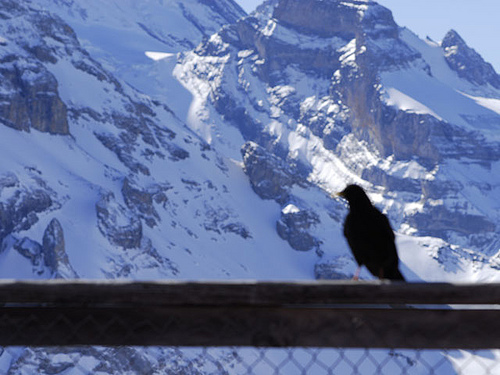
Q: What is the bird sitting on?
A: It is sitting on a railing.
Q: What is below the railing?
A: Open twisted wire fencing.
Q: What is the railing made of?
A: The pieces are made of wood which are separated.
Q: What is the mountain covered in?
A: Snow.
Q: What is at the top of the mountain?
A: A wide circular peak.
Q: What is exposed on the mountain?
A: Layers of rock.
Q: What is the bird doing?
A: The bird is profiling against the snowy mountain.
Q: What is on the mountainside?
A: Large Jagged and smooth outcrops.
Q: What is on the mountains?
A: Snow.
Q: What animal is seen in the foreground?
A: Bird.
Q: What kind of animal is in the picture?
A: Bird.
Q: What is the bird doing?
A: Perched on a fence.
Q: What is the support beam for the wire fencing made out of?
A: Wood.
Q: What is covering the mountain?
A: Snow.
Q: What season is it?
A: Winter.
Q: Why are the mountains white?
A: Snow.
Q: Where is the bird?
A: On the fence.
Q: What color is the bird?
A: Black.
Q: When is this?
A: Morning.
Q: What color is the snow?
A: White.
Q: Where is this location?
A: In the mountains.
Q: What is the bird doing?
A: Sitting.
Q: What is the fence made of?
A: Wood and steel.